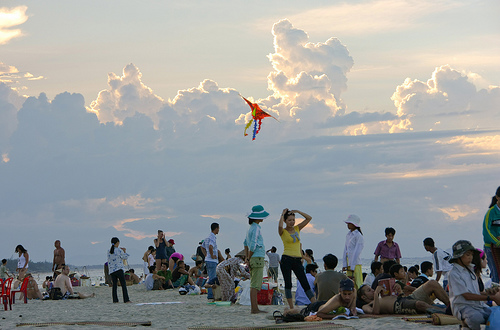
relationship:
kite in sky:
[235, 89, 276, 147] [99, 40, 448, 211]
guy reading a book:
[356, 275, 437, 327] [373, 275, 402, 301]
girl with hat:
[231, 196, 317, 301] [246, 200, 271, 221]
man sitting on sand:
[51, 258, 95, 301] [53, 300, 117, 327]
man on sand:
[51, 258, 95, 301] [53, 300, 117, 327]